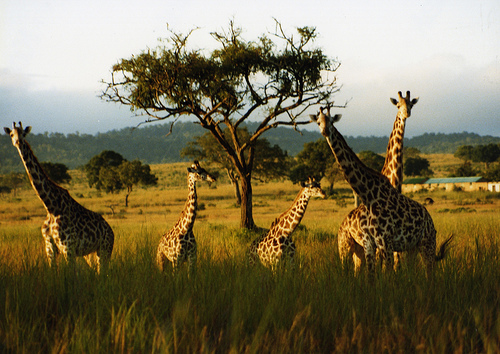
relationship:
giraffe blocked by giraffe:
[340, 90, 418, 278] [309, 107, 454, 280]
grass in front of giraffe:
[2, 201, 500, 352] [340, 90, 418, 278]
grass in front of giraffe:
[2, 201, 500, 352] [309, 107, 454, 280]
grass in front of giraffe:
[2, 201, 500, 352] [246, 177, 326, 272]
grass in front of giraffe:
[2, 201, 500, 352] [156, 159, 216, 280]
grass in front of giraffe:
[2, 201, 500, 352] [3, 120, 115, 276]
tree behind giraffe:
[96, 15, 352, 229] [309, 107, 454, 280]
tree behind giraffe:
[96, 15, 352, 229] [340, 90, 418, 278]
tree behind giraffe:
[96, 15, 352, 229] [246, 177, 326, 272]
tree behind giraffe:
[96, 15, 352, 229] [156, 159, 216, 280]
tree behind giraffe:
[96, 15, 352, 229] [3, 120, 115, 276]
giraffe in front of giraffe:
[309, 107, 454, 280] [340, 90, 418, 278]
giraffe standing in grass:
[156, 159, 216, 280] [2, 201, 500, 352]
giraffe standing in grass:
[246, 177, 326, 272] [2, 201, 500, 352]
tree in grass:
[96, 15, 352, 229] [2, 201, 500, 352]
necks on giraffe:
[323, 139, 409, 178] [309, 107, 454, 280]